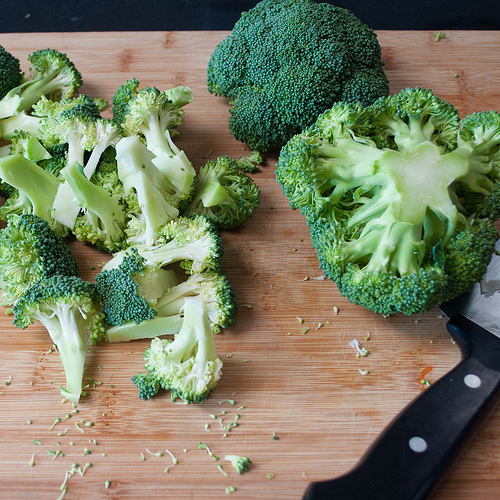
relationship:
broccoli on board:
[10, 39, 498, 347] [3, 33, 498, 497]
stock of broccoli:
[380, 145, 465, 217] [10, 39, 498, 347]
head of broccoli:
[225, 25, 394, 108] [10, 39, 498, 347]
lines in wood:
[259, 374, 333, 404] [19, 36, 459, 498]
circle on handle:
[393, 421, 444, 466] [319, 317, 496, 499]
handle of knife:
[319, 317, 496, 499] [290, 215, 496, 498]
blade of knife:
[437, 241, 498, 308] [290, 215, 496, 498]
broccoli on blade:
[10, 39, 498, 347] [437, 241, 498, 308]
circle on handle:
[405, 435, 427, 455] [319, 317, 496, 499]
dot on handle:
[455, 375, 495, 404] [319, 317, 496, 499]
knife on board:
[290, 215, 496, 498] [3, 33, 498, 497]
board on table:
[3, 33, 498, 497] [19, 5, 479, 26]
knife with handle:
[290, 215, 496, 498] [319, 317, 496, 499]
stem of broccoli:
[36, 322, 97, 398] [10, 39, 498, 347]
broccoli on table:
[10, 39, 498, 347] [19, 5, 479, 26]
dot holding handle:
[461, 372, 481, 390] [319, 317, 496, 499]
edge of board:
[25, 22, 365, 42] [3, 33, 498, 497]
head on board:
[225, 25, 394, 108] [3, 33, 498, 497]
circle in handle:
[405, 435, 427, 455] [319, 317, 496, 499]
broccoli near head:
[10, 39, 498, 347] [225, 25, 394, 108]